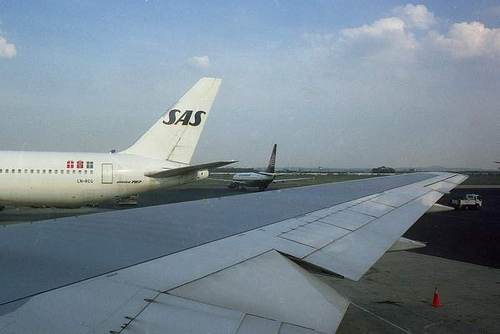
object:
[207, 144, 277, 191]
plan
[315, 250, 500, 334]
tarmac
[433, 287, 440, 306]
traffic cone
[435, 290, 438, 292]
strip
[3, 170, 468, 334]
wing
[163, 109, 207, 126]
writing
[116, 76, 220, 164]
tail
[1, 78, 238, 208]
plane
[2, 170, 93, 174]
row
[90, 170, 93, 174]
windows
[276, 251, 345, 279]
hole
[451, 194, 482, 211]
truck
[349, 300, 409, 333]
line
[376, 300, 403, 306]
spot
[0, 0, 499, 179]
sky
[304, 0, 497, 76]
clouds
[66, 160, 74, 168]
flags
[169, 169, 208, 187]
side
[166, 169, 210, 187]
engine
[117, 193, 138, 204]
stablizer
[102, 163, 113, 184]
door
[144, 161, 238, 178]
wing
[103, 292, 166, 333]
rivets